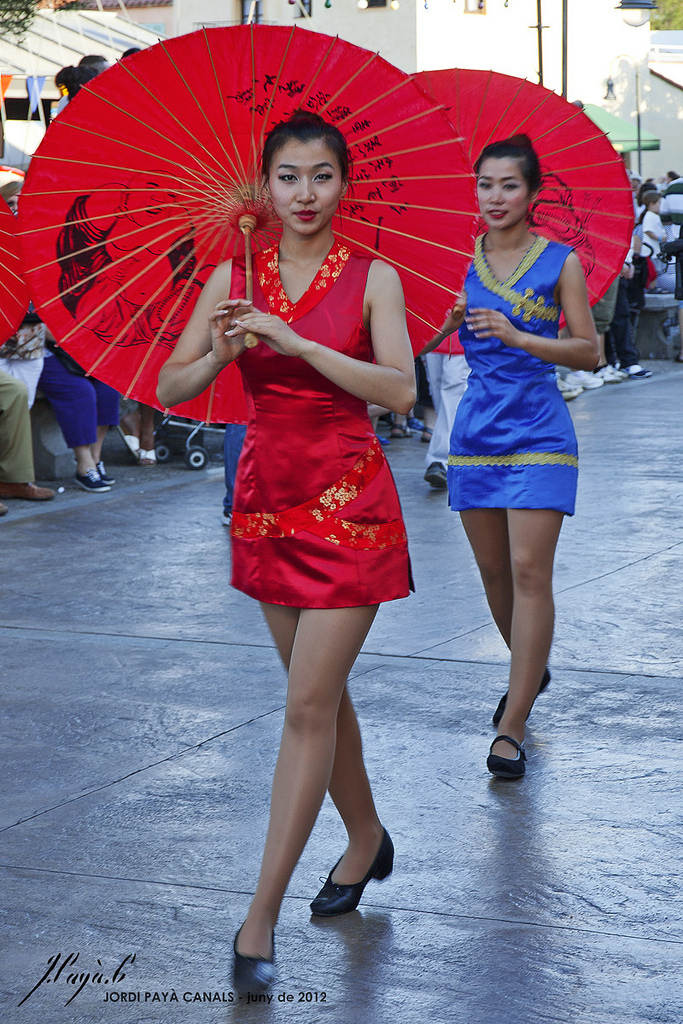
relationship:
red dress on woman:
[226, 248, 425, 609] [158, 108, 427, 995]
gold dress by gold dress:
[444, 233, 577, 514] [444, 233, 577, 513]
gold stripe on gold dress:
[470, 234, 557, 324] [444, 233, 577, 513]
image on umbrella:
[55, 167, 219, 353] [18, 21, 490, 424]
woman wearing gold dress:
[419, 134, 600, 779] [444, 233, 577, 513]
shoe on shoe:
[310, 823, 395, 917] [310, 822, 393, 917]